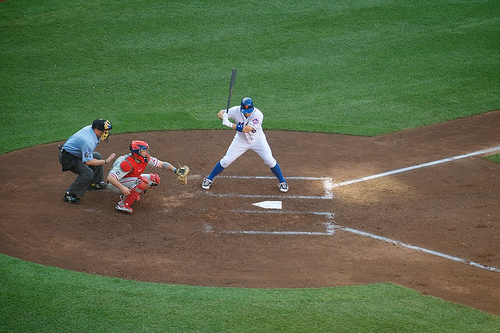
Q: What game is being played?
A: Baseball.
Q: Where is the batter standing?
A: Home plate.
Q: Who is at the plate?
A: A baseball player.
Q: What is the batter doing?
A: Watching the pitch.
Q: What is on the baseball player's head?
A: A blue helmet.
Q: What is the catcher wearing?
A: Red catcher's gear.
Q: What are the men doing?
A: Playing baseball.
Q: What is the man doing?
A: Swinging a baseball bat.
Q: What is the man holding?
A: Baseball bat.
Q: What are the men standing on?
A: Dirt.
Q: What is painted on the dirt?
A: White lines.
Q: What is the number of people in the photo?
A: Three.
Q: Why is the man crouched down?
A: Catcher.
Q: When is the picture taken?
A: Daytime.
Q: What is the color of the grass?
A: Green.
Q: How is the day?
A: Sunny.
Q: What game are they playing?
A: Baseball.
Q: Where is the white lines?
A: In the ground.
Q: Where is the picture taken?
A: At a baseball game.